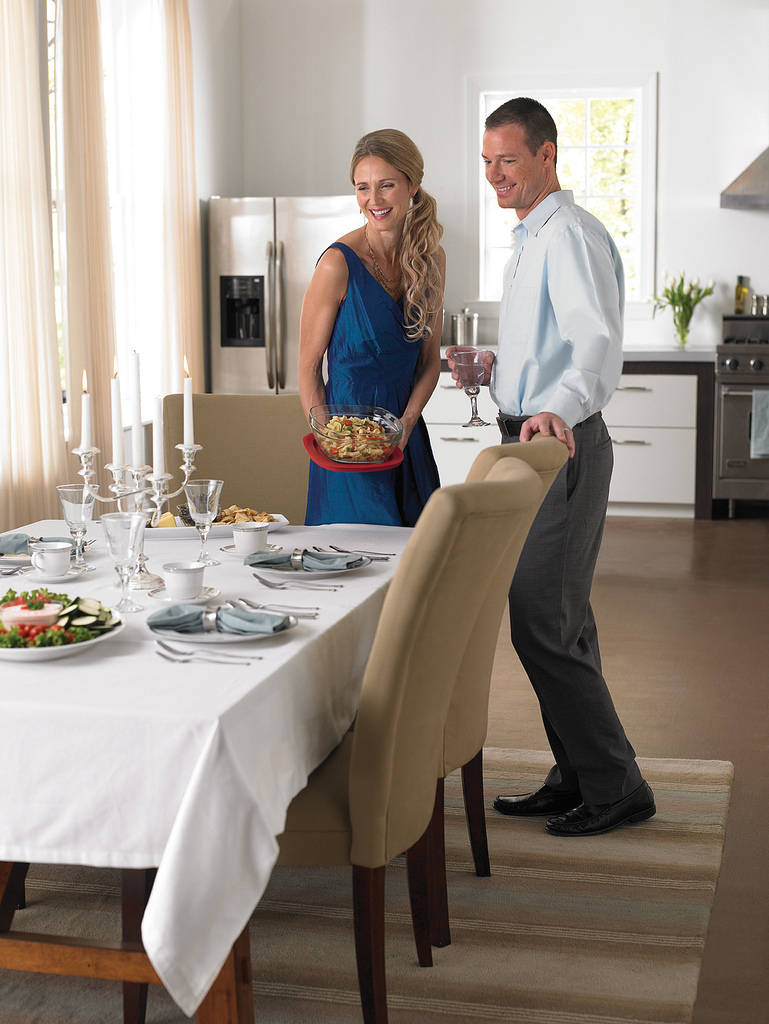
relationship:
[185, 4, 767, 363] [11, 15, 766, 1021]
wall on building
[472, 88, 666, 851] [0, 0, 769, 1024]
person stand building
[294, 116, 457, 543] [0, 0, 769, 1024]
person stand building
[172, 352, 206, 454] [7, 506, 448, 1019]
candle on table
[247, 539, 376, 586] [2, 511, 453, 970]
plate on table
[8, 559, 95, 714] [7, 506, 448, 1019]
plate on table